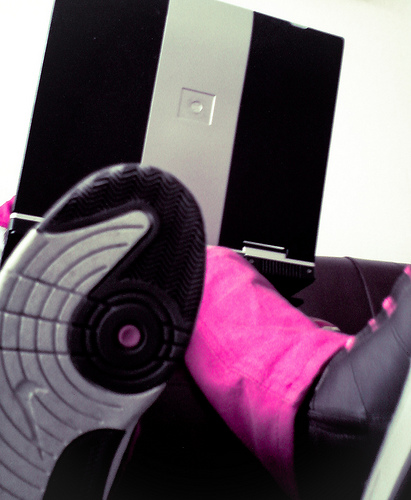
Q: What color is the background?
A: White.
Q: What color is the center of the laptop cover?
A: Gray.